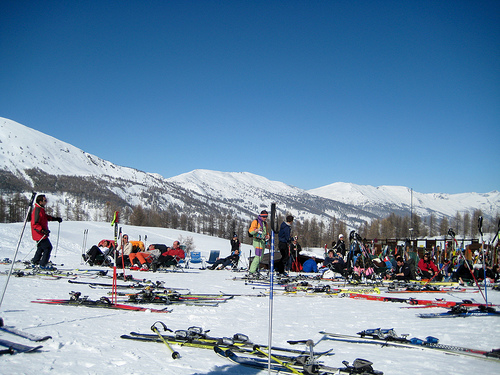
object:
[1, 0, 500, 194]
sky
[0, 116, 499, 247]
mountain range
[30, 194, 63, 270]
man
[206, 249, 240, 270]
man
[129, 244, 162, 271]
person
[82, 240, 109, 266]
person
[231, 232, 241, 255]
person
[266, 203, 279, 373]
ski pole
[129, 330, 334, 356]
ski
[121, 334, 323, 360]
ski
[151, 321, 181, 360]
ski pole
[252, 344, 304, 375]
ski pole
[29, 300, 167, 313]
ski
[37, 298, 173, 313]
ski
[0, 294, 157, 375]
ground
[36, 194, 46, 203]
hair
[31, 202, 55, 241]
jacket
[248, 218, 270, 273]
outfit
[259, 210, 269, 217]
hat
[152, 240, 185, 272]
person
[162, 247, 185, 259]
jacket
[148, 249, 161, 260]
jacket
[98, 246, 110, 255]
jacket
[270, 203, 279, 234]
handle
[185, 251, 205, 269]
chair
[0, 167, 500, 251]
wooded area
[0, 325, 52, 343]
ski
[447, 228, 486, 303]
ski pole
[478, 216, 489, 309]
ski pole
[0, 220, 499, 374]
skiing area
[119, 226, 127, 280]
ski pole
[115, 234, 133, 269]
person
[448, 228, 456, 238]
handle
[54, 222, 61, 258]
ski pole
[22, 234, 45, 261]
ski pole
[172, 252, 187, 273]
chair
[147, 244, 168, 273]
chair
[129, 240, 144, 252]
chair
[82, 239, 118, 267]
chair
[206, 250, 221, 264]
chair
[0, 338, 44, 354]
ski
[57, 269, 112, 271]
ski